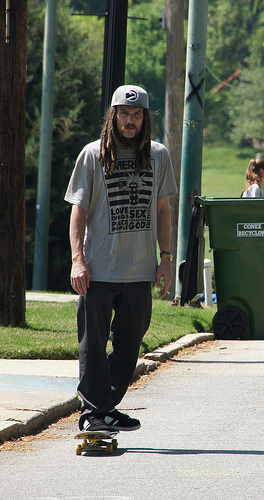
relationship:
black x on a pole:
[186, 70, 212, 114] [175, 3, 207, 306]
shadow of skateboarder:
[119, 443, 263, 458] [64, 82, 177, 433]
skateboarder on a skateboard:
[64, 82, 177, 433] [74, 428, 119, 460]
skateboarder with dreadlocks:
[64, 82, 177, 433] [99, 105, 157, 174]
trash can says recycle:
[179, 194, 262, 343] [237, 232, 264, 240]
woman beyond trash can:
[241, 155, 264, 198] [179, 194, 262, 343]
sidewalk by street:
[0, 361, 80, 441] [8, 337, 264, 499]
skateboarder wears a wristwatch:
[64, 82, 177, 433] [158, 250, 177, 263]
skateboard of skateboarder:
[74, 428, 119, 460] [64, 82, 177, 433]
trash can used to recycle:
[179, 194, 262, 343] [237, 232, 264, 240]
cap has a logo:
[110, 84, 149, 115] [122, 89, 139, 104]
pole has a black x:
[175, 3, 207, 306] [186, 70, 212, 114]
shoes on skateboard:
[83, 412, 144, 433] [74, 428, 119, 460]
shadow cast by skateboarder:
[119, 443, 263, 458] [64, 82, 177, 433]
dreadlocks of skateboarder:
[99, 105, 157, 174] [64, 82, 177, 433]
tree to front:
[19, 2, 107, 294] [2, 299, 210, 454]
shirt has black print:
[63, 139, 179, 285] [109, 151, 153, 233]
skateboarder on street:
[64, 82, 177, 433] [8, 337, 264, 499]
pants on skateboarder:
[80, 283, 153, 417] [64, 82, 177, 433]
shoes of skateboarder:
[83, 412, 144, 433] [64, 82, 177, 433]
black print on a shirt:
[109, 151, 153, 233] [63, 139, 179, 285]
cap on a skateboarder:
[110, 84, 149, 115] [64, 82, 177, 433]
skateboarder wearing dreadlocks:
[64, 82, 177, 433] [99, 105, 157, 174]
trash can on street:
[179, 194, 262, 343] [8, 337, 264, 499]